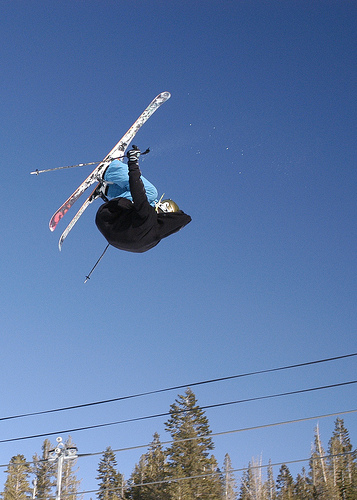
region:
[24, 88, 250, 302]
a person in the air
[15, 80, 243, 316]
a person skiing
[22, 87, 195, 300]
a person wearing a helmet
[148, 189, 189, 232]
the helmet is gold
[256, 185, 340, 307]
the sky is blue and clear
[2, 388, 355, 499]
the pine trees with green leaves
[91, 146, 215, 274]
the person wearing pants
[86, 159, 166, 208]
the pants are blue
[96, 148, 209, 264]
the person wearing a jacket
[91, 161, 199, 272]
the jacket is black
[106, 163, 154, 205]
the pants are blue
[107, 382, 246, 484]
electrical wires are in the air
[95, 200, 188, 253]
the jumper is black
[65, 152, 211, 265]
the guy is upside down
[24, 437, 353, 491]
trees are in the background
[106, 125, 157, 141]
the skateboard has graphic on it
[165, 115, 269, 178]
snow patches are in the air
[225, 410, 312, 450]
the sky is cloudless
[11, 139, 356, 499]
the photo was taken outdoors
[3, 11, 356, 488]
the photo was taken in the daytime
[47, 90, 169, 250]
black, red, and white skiis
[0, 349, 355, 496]
powerlines going across sky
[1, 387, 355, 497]
tall trees behind powerlines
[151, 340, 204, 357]
bright blue clear sky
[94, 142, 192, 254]
snow skier in midair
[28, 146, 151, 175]
left red and black ski pole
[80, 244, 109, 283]
right black and white ski pole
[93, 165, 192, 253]
heavy black coat on skier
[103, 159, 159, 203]
light blue pants on snow skier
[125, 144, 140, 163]
left black and white glove on skier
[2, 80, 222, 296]
A skier up in the air.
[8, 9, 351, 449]
The sky is clear and blue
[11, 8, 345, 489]
Photo taken during the day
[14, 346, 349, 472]
Telephone wires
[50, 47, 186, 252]
Skis on the man's feet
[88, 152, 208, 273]
Black hoodie on the skier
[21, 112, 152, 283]
Poles in the skier's hands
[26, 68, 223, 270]
Skier doing a trick in the air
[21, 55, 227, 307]
One person in the photo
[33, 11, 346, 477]
Photo taken during the winter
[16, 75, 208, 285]
skier doing a trick in the air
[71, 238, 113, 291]
a pole on right hand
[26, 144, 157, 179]
a pole on left hand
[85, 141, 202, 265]
skier wears a black coat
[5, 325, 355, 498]
four wires pass across the picture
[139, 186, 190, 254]
skier wears a helmet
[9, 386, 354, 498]
trees of different sizes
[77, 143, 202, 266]
man has blue pants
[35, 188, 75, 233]
back of ski is pink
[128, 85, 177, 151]
front of ski is white and blue